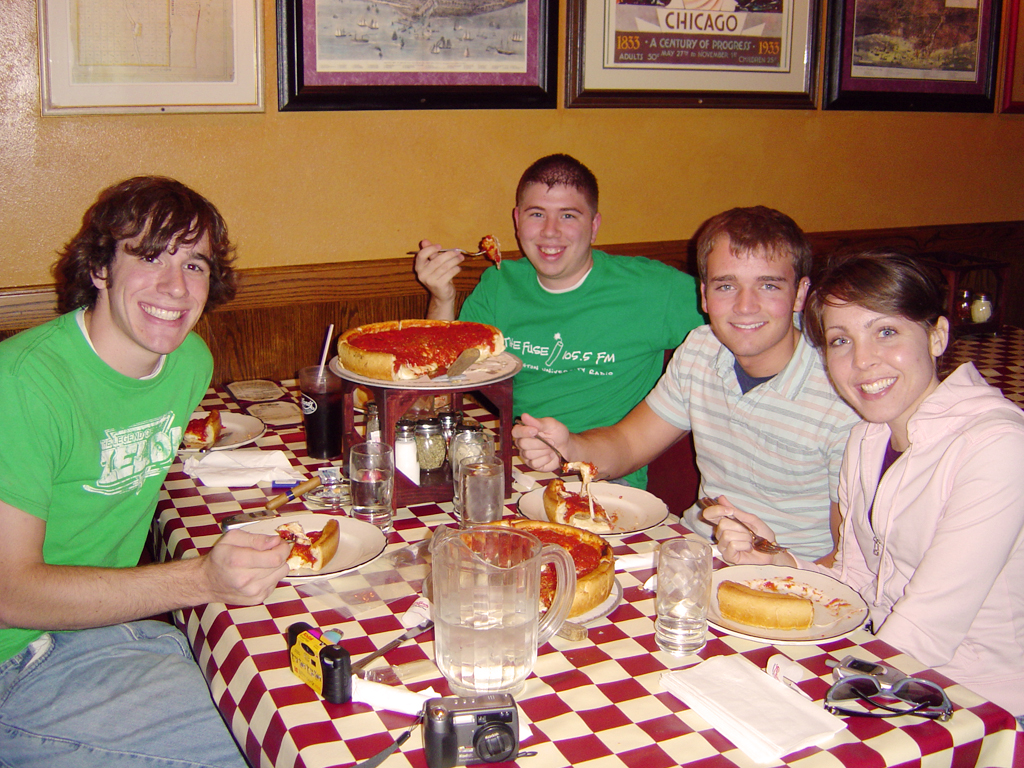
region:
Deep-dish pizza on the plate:
[327, 296, 521, 399]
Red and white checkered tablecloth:
[145, 374, 1021, 766]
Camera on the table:
[422, 688, 525, 765]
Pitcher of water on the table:
[410, 521, 575, 690]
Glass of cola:
[296, 359, 341, 462]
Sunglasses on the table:
[827, 664, 952, 718]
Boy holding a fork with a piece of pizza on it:
[406, 142, 701, 485]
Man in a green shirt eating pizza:
[0, 169, 396, 739]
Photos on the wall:
[31, 0, 1019, 119]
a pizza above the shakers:
[331, 285, 521, 397]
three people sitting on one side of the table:
[476, 145, 1021, 709]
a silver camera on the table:
[367, 686, 533, 764]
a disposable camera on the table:
[280, 616, 367, 705]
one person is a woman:
[714, 250, 1022, 725]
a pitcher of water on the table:
[407, 521, 586, 699]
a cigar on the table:
[264, 476, 326, 506]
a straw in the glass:
[315, 310, 338, 391]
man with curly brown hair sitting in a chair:
[0, 175, 291, 767]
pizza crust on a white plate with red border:
[705, 561, 874, 647]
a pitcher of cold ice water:
[430, 523, 570, 695]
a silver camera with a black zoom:
[351, 693, 525, 767]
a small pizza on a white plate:
[430, 514, 626, 633]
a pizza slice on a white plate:
[223, 508, 389, 585]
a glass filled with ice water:
[653, 536, 715, 655]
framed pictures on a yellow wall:
[7, 0, 1014, 283]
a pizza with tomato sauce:
[326, 314, 519, 387]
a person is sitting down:
[9, 180, 240, 765]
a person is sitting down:
[529, 217, 840, 546]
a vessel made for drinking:
[647, 528, 714, 668]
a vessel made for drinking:
[445, 456, 521, 510]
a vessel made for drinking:
[343, 433, 398, 516]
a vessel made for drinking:
[295, 361, 347, 451]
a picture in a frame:
[278, 7, 567, 100]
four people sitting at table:
[4, 107, 1022, 765]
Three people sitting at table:
[450, 141, 1020, 609]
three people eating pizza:
[315, 139, 1014, 719]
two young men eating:
[4, 119, 654, 699]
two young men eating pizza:
[2, 117, 644, 703]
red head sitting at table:
[791, 239, 1022, 720]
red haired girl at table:
[803, 224, 1022, 759]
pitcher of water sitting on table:
[394, 509, 607, 722]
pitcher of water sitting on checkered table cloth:
[427, 514, 579, 702]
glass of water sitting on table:
[639, 524, 729, 684]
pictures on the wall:
[35, 6, 991, 104]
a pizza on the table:
[343, 326, 515, 383]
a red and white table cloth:
[164, 357, 769, 743]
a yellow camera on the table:
[296, 632, 351, 687]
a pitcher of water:
[432, 527, 546, 682]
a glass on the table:
[653, 534, 696, 652]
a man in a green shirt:
[454, 158, 673, 462]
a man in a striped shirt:
[679, 236, 822, 515]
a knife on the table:
[362, 628, 424, 674]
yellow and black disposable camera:
[282, 619, 358, 708]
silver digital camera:
[415, 689, 521, 765]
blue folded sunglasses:
[819, 670, 952, 719]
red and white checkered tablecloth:
[156, 367, 1010, 759]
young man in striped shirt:
[519, 199, 827, 567]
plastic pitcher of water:
[413, 518, 573, 703]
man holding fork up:
[409, 152, 684, 486]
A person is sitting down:
[755, 266, 1016, 726]